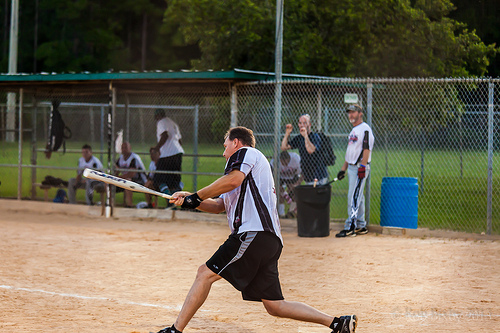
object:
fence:
[395, 74, 499, 221]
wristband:
[184, 195, 194, 205]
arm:
[200, 161, 256, 194]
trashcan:
[381, 176, 421, 229]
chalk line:
[0, 275, 196, 322]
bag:
[48, 101, 72, 155]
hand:
[151, 145, 160, 156]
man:
[144, 104, 184, 214]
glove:
[181, 193, 203, 211]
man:
[142, 125, 359, 333]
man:
[335, 102, 375, 238]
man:
[110, 142, 149, 209]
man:
[67, 142, 105, 206]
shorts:
[206, 227, 284, 303]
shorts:
[150, 153, 184, 186]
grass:
[2, 138, 499, 236]